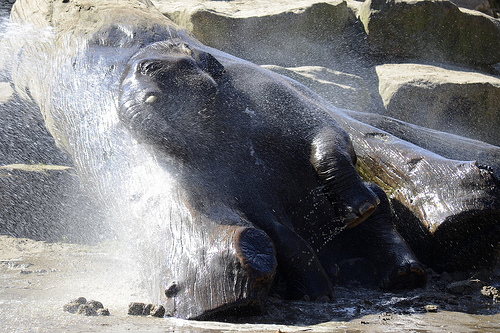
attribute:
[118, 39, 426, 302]
elephant — big, black, wet, leaning over, being sprayed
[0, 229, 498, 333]
ground — wet, dirty, dirt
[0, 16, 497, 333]
water — sprayed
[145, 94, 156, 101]
tusky — short, white, small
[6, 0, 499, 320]
log — wet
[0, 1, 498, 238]
rocks — grey, wet, dirty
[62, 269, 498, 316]
rocks — small, wet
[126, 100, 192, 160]
trunk — curled